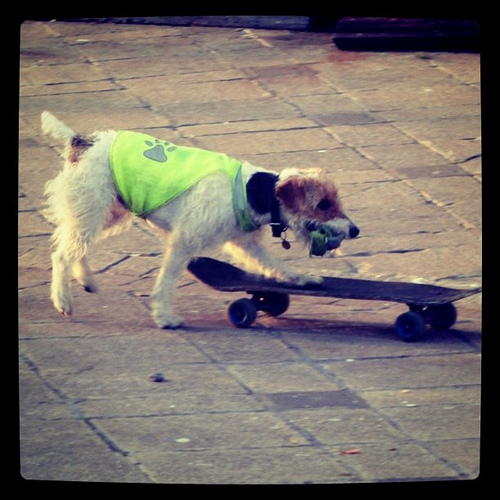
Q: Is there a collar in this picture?
A: Yes, there is a collar.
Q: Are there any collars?
A: Yes, there is a collar.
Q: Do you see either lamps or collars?
A: Yes, there is a collar.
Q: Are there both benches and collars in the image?
A: No, there is a collar but no benches.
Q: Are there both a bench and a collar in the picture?
A: No, there is a collar but no benches.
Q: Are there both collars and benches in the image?
A: No, there is a collar but no benches.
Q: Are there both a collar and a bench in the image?
A: No, there is a collar but no benches.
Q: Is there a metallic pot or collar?
A: Yes, there is a metal collar.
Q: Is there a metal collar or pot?
A: Yes, there is a metal collar.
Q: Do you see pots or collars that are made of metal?
A: Yes, the collar is made of metal.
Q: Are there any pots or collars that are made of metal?
A: Yes, the collar is made of metal.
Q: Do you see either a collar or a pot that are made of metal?
A: Yes, the collar is made of metal.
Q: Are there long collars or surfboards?
A: Yes, there is a long collar.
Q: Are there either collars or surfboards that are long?
A: Yes, the collar is long.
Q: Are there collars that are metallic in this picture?
A: Yes, there is a metal collar.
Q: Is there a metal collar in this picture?
A: Yes, there is a metal collar.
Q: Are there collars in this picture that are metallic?
A: Yes, there is a collar that is metallic.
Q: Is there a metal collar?
A: Yes, there is a collar that is made of metal.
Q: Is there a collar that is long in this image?
A: Yes, there is a long collar.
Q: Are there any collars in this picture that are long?
A: Yes, there is a collar that is long.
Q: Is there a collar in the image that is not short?
A: Yes, there is a long collar.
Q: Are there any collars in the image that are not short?
A: Yes, there is a long collar.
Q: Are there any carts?
A: No, there are no carts.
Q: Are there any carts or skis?
A: No, there are no carts or skis.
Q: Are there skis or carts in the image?
A: No, there are no carts or skis.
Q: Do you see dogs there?
A: Yes, there is a dog.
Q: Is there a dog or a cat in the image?
A: Yes, there is a dog.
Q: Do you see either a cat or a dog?
A: Yes, there is a dog.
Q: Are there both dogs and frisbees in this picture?
A: No, there is a dog but no frisbees.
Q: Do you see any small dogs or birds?
A: Yes, there is a small dog.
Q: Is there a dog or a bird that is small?
A: Yes, the dog is small.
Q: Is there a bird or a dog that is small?
A: Yes, the dog is small.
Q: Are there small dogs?
A: Yes, there is a small dog.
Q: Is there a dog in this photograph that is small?
A: Yes, there is a dog that is small.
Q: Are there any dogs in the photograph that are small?
A: Yes, there is a dog that is small.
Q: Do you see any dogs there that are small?
A: Yes, there is a dog that is small.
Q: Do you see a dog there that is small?
A: Yes, there is a dog that is small.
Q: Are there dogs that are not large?
A: Yes, there is a small dog.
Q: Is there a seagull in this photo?
A: No, there are no seagulls.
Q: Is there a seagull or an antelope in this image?
A: No, there are no seagulls or antelopes.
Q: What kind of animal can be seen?
A: The animal is a dog.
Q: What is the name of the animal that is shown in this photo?
A: The animal is a dog.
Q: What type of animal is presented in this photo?
A: The animal is a dog.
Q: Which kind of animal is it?
A: The animal is a dog.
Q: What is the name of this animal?
A: This is a dog.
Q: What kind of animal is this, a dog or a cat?
A: This is a dog.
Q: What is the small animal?
A: The animal is a dog.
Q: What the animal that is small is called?
A: The animal is a dog.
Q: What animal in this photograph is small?
A: The animal is a dog.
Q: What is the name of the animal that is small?
A: The animal is a dog.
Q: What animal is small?
A: The animal is a dog.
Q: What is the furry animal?
A: The animal is a dog.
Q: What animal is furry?
A: The animal is a dog.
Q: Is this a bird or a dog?
A: This is a dog.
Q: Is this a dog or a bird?
A: This is a dog.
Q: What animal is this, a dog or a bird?
A: This is a dog.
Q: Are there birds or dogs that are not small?
A: No, there is a dog but it is small.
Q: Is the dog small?
A: Yes, the dog is small.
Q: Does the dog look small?
A: Yes, the dog is small.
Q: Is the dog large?
A: No, the dog is small.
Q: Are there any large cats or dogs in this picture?
A: No, there is a dog but it is small.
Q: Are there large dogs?
A: No, there is a dog but it is small.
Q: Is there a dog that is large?
A: No, there is a dog but it is small.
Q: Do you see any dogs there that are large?
A: No, there is a dog but it is small.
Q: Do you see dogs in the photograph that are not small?
A: No, there is a dog but it is small.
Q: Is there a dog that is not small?
A: No, there is a dog but it is small.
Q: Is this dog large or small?
A: The dog is small.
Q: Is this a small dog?
A: Yes, this is a small dog.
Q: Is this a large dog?
A: No, this is a small dog.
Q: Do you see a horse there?
A: No, there are no horses.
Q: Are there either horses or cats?
A: No, there are no horses or cats.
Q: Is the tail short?
A: Yes, the tail is short.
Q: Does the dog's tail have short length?
A: Yes, the tail is short.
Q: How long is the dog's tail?
A: The tail is short.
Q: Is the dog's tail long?
A: No, the tail is short.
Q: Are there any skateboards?
A: Yes, there is a skateboard.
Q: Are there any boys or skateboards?
A: Yes, there is a skateboard.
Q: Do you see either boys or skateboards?
A: Yes, there is a skateboard.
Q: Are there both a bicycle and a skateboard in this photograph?
A: No, there is a skateboard but no bicycles.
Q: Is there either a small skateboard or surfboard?
A: Yes, there is a small skateboard.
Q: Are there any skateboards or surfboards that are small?
A: Yes, the skateboard is small.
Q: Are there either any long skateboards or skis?
A: Yes, there is a long skateboard.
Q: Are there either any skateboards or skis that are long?
A: Yes, the skateboard is long.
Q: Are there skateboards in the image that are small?
A: Yes, there is a small skateboard.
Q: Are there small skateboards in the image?
A: Yes, there is a small skateboard.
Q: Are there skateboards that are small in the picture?
A: Yes, there is a small skateboard.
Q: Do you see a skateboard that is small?
A: Yes, there is a skateboard that is small.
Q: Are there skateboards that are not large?
A: Yes, there is a small skateboard.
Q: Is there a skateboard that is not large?
A: Yes, there is a small skateboard.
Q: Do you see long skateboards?
A: Yes, there is a long skateboard.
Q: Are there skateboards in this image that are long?
A: Yes, there is a skateboard that is long.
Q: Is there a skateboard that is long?
A: Yes, there is a skateboard that is long.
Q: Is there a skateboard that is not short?
A: Yes, there is a long skateboard.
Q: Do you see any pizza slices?
A: No, there are no pizza slices.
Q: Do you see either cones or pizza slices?
A: No, there are no pizza slices or cones.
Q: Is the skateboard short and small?
A: No, the skateboard is small but long.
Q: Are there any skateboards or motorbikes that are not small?
A: No, there is a skateboard but it is small.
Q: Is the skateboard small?
A: Yes, the skateboard is small.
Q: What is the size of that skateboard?
A: The skateboard is small.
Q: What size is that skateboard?
A: The skateboard is small.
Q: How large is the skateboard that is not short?
A: The skateboard is small.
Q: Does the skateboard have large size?
A: No, the skateboard is small.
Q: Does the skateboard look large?
A: No, the skateboard is small.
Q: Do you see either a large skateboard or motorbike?
A: No, there is a skateboard but it is small.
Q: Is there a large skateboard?
A: No, there is a skateboard but it is small.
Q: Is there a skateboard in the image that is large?
A: No, there is a skateboard but it is small.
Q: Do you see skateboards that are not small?
A: No, there is a skateboard but it is small.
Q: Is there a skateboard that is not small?
A: No, there is a skateboard but it is small.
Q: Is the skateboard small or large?
A: The skateboard is small.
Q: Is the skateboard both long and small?
A: Yes, the skateboard is long and small.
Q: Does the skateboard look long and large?
A: No, the skateboard is long but small.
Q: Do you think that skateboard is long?
A: Yes, the skateboard is long.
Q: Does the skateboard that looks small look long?
A: Yes, the skateboard is long.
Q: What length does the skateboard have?
A: The skateboard has long length.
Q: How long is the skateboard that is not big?
A: The skateboard is long.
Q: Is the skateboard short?
A: No, the skateboard is long.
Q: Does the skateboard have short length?
A: No, the skateboard is long.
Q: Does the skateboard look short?
A: No, the skateboard is long.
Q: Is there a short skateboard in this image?
A: No, there is a skateboard but it is long.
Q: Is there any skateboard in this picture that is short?
A: No, there is a skateboard but it is long.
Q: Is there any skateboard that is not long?
A: No, there is a skateboard but it is long.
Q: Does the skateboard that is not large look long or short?
A: The skateboard is long.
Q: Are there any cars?
A: No, there are no cars.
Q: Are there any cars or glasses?
A: No, there are no cars or glasses.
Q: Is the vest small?
A: Yes, the vest is small.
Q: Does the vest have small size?
A: Yes, the vest is small.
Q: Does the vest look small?
A: Yes, the vest is small.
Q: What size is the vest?
A: The vest is small.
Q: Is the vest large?
A: No, the vest is small.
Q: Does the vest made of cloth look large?
A: No, the vest is small.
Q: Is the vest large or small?
A: The vest is small.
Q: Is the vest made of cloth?
A: Yes, the vest is made of cloth.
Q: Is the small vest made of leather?
A: No, the vest is made of cloth.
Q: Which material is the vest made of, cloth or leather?
A: The vest is made of cloth.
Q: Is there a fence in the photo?
A: No, there are no fences.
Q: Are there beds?
A: No, there are no beds.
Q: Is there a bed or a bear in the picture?
A: No, there are no beds or bears.